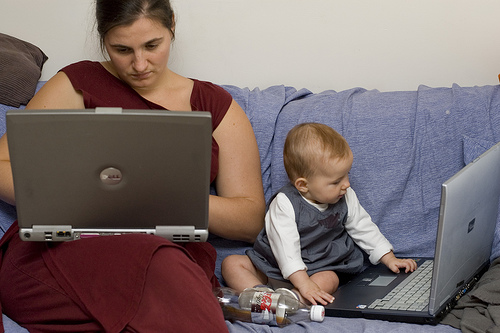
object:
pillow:
[0, 30, 49, 113]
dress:
[247, 189, 366, 279]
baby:
[223, 119, 411, 313]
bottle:
[212, 287, 326, 330]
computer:
[5, 106, 499, 328]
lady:
[3, 1, 268, 329]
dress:
[0, 59, 233, 332]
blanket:
[228, 85, 499, 259]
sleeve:
[261, 188, 307, 279]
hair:
[283, 123, 350, 187]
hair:
[86, 0, 183, 64]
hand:
[382, 244, 418, 276]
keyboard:
[327, 257, 436, 316]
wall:
[0, 0, 500, 89]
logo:
[95, 163, 126, 191]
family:
[0, 0, 420, 332]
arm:
[0, 63, 272, 240]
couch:
[0, 74, 497, 332]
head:
[280, 121, 359, 208]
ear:
[291, 175, 311, 195]